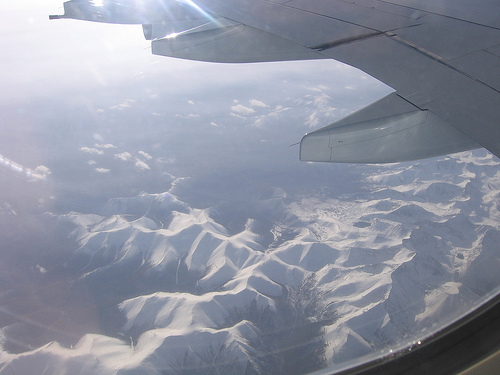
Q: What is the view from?
A: An airplane window.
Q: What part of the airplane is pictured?
A: The wing.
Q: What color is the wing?
A: White.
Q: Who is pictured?
A: No one is pictured.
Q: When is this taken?
A: Daytime.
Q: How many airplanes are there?
A: One.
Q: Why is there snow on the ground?
A: It is winter.